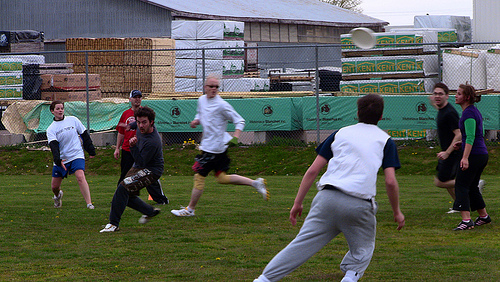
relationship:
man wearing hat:
[112, 89, 170, 206] [129, 85, 143, 100]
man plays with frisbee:
[249, 91, 410, 281] [347, 25, 379, 52]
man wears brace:
[169, 71, 276, 226] [188, 166, 208, 191]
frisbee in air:
[338, 22, 385, 62] [260, 20, 453, 76]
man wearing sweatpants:
[249, 91, 412, 278] [256, 187, 379, 280]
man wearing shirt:
[249, 91, 410, 281] [193, 95, 243, 152]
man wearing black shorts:
[169, 76, 271, 218] [190, 145, 226, 175]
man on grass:
[249, 91, 410, 281] [196, 231, 272, 279]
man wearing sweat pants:
[249, 91, 412, 278] [239, 191, 392, 280]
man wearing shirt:
[249, 91, 412, 278] [316, 120, 398, 201]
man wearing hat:
[112, 87, 167, 207] [124, 82, 144, 99]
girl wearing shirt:
[447, 77, 497, 237] [456, 105, 491, 156]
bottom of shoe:
[259, 178, 273, 204] [249, 173, 271, 201]